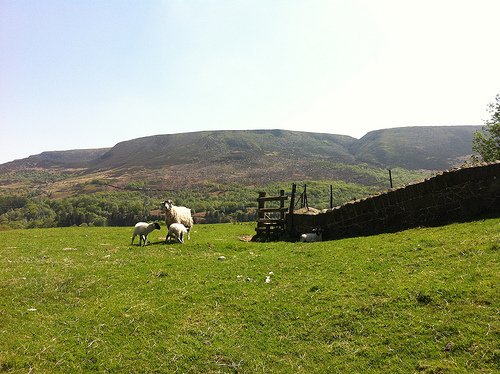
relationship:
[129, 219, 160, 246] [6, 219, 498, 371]
sheep on prairie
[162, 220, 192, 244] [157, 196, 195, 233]
lamb near sheep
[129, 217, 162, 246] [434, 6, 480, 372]
lamb face right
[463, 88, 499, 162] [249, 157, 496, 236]
tree inside a fence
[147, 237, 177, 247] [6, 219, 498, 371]
shadow cast green grass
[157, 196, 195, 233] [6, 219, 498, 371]
sheep on field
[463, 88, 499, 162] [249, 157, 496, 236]
tree on gate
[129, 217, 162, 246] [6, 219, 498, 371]
lamb on field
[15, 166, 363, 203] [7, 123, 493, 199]
bushes by hill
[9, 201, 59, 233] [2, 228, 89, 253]
bush on ground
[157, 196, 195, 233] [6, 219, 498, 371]
sheep standing in field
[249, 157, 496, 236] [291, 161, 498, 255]
wall made of rocks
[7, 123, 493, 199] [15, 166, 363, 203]
mountains covered with trees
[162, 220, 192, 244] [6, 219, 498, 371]
sheep sitting on ground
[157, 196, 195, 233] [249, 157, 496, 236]
sheep next to wall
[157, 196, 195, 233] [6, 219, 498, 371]
sheep in a field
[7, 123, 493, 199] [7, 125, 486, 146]
hills on horizon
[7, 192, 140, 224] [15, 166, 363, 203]
tree in valley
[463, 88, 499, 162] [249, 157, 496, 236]
tree behind wall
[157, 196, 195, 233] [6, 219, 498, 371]
sheep in pasture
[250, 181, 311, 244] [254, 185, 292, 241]
fence has cross bars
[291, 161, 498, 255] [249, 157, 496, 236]
wall mad of stone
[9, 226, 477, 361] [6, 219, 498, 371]
pasture very green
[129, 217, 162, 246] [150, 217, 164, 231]
lamb has black face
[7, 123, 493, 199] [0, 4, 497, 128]
trees in background